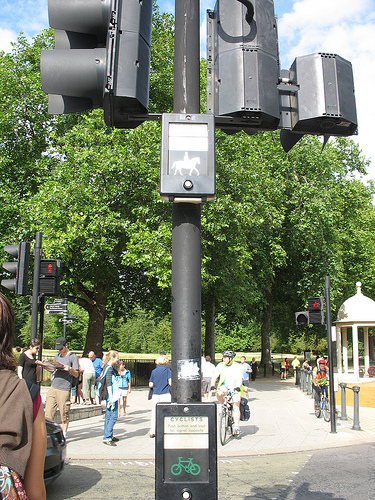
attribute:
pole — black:
[168, 204, 220, 409]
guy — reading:
[40, 334, 81, 392]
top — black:
[16, 353, 41, 390]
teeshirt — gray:
[47, 358, 83, 388]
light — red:
[45, 259, 59, 283]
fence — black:
[128, 355, 152, 398]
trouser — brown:
[40, 380, 73, 432]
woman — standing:
[98, 389, 125, 451]